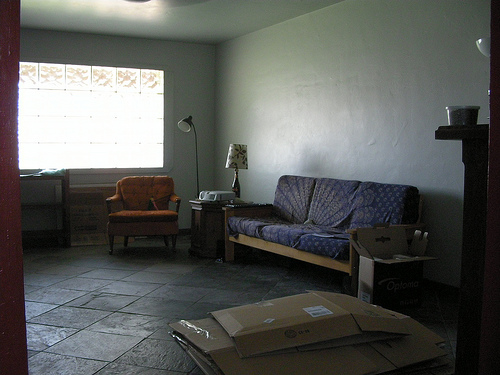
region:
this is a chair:
[224, 155, 417, 272]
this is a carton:
[226, 299, 408, 359]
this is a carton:
[194, 313, 420, 364]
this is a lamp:
[166, 105, 199, 147]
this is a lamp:
[219, 129, 266, 190]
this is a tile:
[74, 278, 138, 324]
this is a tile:
[151, 276, 217, 314]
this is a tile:
[41, 262, 95, 297]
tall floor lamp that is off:
[174, 107, 206, 189]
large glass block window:
[22, 62, 169, 170]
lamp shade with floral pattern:
[221, 142, 251, 171]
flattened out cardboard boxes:
[164, 287, 459, 372]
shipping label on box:
[303, 299, 333, 320]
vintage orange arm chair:
[104, 174, 183, 254]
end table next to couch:
[189, 197, 224, 261]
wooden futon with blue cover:
[220, 176, 425, 289]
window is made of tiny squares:
[20, 59, 165, 167]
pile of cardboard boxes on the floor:
[175, 290, 444, 373]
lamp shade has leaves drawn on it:
[222, 141, 250, 169]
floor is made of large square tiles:
[40, 274, 170, 351]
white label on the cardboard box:
[300, 302, 335, 319]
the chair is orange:
[102, 173, 183, 255]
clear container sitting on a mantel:
[439, 97, 479, 139]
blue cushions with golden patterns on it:
[275, 176, 349, 254]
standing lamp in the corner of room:
[177, 117, 203, 193]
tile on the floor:
[135, 290, 173, 312]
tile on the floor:
[97, 311, 155, 338]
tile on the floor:
[142, 339, 189, 364]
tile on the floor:
[111, 275, 147, 294]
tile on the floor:
[94, 265, 125, 282]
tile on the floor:
[36, 283, 72, 305]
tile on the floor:
[51, 266, 81, 272]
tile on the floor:
[63, 325, 114, 356]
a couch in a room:
[232, 108, 447, 370]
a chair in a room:
[93, 134, 172, 251]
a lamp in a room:
[172, 83, 239, 259]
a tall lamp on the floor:
[141, 112, 238, 264]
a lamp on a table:
[187, 125, 275, 239]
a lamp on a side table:
[212, 133, 307, 221]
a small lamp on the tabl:
[209, 127, 258, 222]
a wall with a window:
[52, 36, 264, 228]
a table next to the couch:
[189, 161, 289, 276]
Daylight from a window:
[50, 94, 126, 151]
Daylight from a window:
[60, 108, 137, 152]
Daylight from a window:
[51, 112, 144, 158]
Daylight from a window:
[42, 89, 139, 149]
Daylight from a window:
[46, 100, 143, 154]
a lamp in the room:
[177, 108, 199, 195]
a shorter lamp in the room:
[224, 137, 252, 200]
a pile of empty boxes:
[164, 288, 448, 374]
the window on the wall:
[19, 59, 168, 176]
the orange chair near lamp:
[99, 168, 186, 255]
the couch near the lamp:
[226, 170, 426, 291]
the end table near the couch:
[187, 187, 248, 269]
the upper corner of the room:
[201, 30, 226, 60]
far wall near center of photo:
[20, 36, 215, 252]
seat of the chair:
[111, 205, 174, 217]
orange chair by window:
[90, 163, 201, 258]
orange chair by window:
[91, 166, 199, 266]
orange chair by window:
[90, 168, 194, 268]